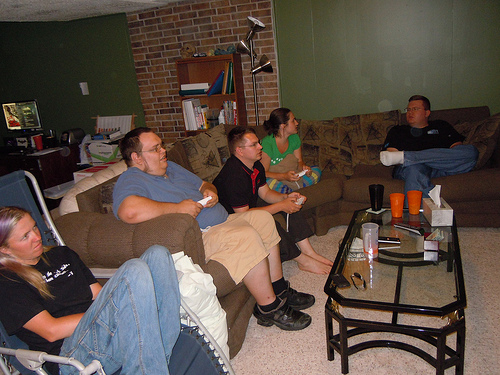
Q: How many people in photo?
A: Five.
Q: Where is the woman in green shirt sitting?
A: On couch.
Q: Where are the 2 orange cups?
A: Coffee table.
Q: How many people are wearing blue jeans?
A: Two.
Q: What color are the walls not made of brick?
A: Green.